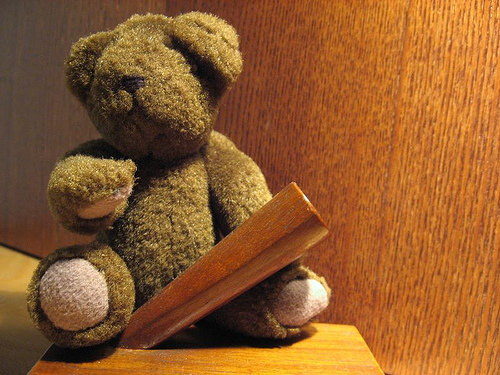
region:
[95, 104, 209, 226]
A stuffed toy is visible.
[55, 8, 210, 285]
A stuffed toy is visible.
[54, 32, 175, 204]
A stuffed toy is visible.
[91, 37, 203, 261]
A stuffed toy is visible.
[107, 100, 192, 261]
A stuffed toy is visible.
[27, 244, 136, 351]
a teddy bear's right foot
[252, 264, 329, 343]
a teddy bear's left foot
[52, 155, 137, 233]
a teddy bear's right paw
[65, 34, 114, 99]
a teddy bear's right ear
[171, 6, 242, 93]
a teddy bear's left ear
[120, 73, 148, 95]
a teddy bear's nose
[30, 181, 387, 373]
a wooden stand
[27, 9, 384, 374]
a teddy bear on a wood stand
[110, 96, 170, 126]
a teddy bear's mouth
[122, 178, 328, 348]
piece of wood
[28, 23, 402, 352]
one little teddy bear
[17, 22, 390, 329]
one cute little teddy bear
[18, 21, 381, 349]
one fluffy little teddy bear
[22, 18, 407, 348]
one cuddly little teddy bear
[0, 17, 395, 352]
one soft little teddy bear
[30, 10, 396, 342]
one loveable little teddy bear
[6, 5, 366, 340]
one single little teddy bear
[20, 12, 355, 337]
one plump little teddy bear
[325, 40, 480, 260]
piece of wood wall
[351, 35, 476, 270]
piece of brown wood wall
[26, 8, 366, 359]
The teddy bear is brown.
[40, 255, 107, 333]
The bottom of the foot is pink.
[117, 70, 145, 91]
The teddy bear has a dark brown nose.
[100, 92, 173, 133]
The teddy bear has a mouth.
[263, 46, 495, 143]
The wall is made of wood.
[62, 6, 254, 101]
The teddy bear has two ears.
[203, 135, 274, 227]
An arm on the teddy bear.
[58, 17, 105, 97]
An ear on the teddy bear.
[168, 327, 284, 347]
The shadow under a teddy bear.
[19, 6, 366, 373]
The teddy bear is sitting on a wood box.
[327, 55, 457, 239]
a brown paneled wall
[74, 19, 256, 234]
a soft brown teddy bear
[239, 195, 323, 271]
a small wooden handle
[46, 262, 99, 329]
a round white foot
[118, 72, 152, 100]
a dark brown nose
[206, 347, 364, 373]
a brown wooden surface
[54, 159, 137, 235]
a raise brown and white paw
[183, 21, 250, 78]
a fluffy ear on the bear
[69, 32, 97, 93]
another ear on the bear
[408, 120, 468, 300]
tiny black grains in the wood